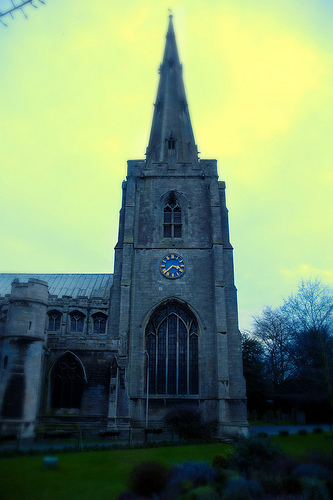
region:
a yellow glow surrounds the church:
[2, 2, 331, 280]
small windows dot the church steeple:
[145, 5, 202, 163]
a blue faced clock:
[161, 253, 185, 280]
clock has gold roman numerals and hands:
[159, 253, 186, 281]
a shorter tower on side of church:
[1, 270, 40, 442]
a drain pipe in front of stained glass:
[140, 343, 152, 431]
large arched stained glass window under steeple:
[142, 295, 201, 402]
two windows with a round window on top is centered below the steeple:
[154, 185, 190, 242]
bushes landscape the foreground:
[121, 436, 332, 499]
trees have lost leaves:
[246, 275, 332, 384]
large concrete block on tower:
[212, 399, 231, 424]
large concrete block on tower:
[215, 376, 230, 402]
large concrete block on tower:
[209, 326, 232, 384]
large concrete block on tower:
[207, 280, 230, 335]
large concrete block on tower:
[206, 237, 230, 290]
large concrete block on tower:
[204, 198, 227, 247]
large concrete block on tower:
[119, 200, 138, 243]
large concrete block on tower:
[112, 237, 133, 290]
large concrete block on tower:
[112, 276, 131, 358]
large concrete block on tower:
[123, 155, 225, 181]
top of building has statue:
[157, 1, 187, 13]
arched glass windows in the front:
[146, 305, 195, 404]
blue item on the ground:
[43, 450, 59, 476]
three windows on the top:
[46, 306, 112, 348]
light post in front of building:
[140, 335, 149, 437]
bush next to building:
[168, 417, 213, 452]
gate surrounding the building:
[20, 424, 178, 449]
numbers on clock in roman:
[151, 253, 191, 281]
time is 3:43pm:
[146, 244, 186, 282]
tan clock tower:
[100, 1, 254, 433]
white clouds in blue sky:
[241, 132, 276, 176]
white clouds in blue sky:
[242, 211, 294, 244]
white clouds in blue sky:
[205, 27, 236, 77]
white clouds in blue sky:
[8, 149, 55, 183]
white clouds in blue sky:
[5, 125, 75, 221]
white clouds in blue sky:
[65, 82, 95, 132]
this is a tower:
[111, 13, 267, 453]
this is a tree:
[258, 306, 287, 419]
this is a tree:
[246, 329, 274, 432]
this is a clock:
[158, 252, 189, 283]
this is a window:
[161, 193, 185, 241]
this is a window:
[89, 312, 104, 336]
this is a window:
[65, 306, 87, 339]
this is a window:
[39, 302, 64, 344]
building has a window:
[162, 205, 172, 234]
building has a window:
[146, 300, 200, 393]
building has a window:
[66, 310, 84, 331]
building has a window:
[91, 311, 106, 333]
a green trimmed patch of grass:
[2, 464, 30, 496]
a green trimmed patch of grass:
[29, 464, 60, 492]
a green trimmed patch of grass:
[65, 453, 94, 478]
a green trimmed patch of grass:
[64, 473, 95, 497]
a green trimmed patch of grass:
[98, 475, 126, 498]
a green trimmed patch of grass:
[159, 441, 189, 466]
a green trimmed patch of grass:
[190, 442, 221, 464]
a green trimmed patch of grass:
[283, 433, 315, 461]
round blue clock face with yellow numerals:
[158, 253, 187, 279]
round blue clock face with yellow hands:
[158, 251, 186, 280]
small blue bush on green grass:
[170, 457, 212, 480]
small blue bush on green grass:
[223, 473, 258, 493]